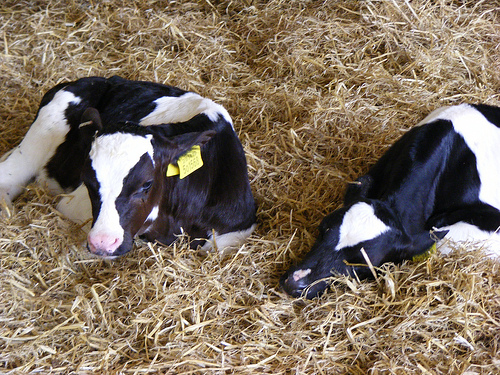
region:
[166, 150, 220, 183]
Yellow tag on cow's ear.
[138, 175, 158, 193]
Cow has dark eye.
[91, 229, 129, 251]
Cow has pink nose.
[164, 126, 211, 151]
Cow has black ear.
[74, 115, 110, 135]
Cow has black ear.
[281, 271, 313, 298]
Cow has black nose.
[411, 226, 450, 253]
Cow has black ear.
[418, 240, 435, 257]
Yellow tag on cow's ear.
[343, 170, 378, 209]
Cow has black ear.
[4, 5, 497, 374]
a scene in a barn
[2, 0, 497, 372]
a scene inside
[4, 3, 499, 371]
a patch of hay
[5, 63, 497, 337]
two animals laying down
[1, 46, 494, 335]
two black and white cows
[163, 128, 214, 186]
a yellow tag on ear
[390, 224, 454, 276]
a yellow tag on ear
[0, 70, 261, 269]
a black and white cow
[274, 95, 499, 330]
a black and white cow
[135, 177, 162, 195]
a cow eyeball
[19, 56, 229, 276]
the cow is resting on hay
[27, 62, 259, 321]
the cow is resting on hay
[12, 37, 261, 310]
the cow is resting on hay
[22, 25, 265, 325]
the cow is resting on hay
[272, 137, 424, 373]
the cow is sleeping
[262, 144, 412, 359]
the cow is sleeping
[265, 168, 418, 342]
the cow is sleeping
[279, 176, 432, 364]
the cow is sleeping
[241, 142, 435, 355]
the cow is sleeping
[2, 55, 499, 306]
two black and white calves in the straw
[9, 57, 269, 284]
black and white calf has a yellow tag in his ear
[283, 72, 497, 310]
black and white calf has a white triange on his head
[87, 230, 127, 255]
soft pink nose on a calf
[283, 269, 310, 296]
soft black nose on a black and white calf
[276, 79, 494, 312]
calf is laying in the straw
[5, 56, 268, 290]
calf is reclining in the straw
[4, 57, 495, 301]
two relaxed calves in the yellow straw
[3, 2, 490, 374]
huge pile of straw under two calves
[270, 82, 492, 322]
calf is asleep in the straw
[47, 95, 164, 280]
head of a cow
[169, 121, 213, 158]
ear of a cow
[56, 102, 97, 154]
ear of a cow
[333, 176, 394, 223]
ear of a cow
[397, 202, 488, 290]
ear of a cow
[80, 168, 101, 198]
eye of a cow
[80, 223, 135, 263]
nose of a cow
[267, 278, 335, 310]
mouth of a cow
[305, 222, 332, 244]
eye of a cow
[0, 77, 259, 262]
cow is laying in the hay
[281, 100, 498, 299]
cow is laying in the hay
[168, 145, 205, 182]
paper attached to cows ear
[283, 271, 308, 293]
nose is apart of cow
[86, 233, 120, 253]
nose is apart of cow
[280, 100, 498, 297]
a black and white calf with a black nose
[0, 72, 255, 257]
a black and white calf with a pink nose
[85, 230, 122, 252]
the calf's pink nose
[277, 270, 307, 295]
the calf's black nose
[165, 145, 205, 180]
yellow tag in the calf's ear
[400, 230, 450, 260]
the calf's left ear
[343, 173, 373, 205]
the calf's right ear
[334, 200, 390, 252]
the white spot on the calf's head